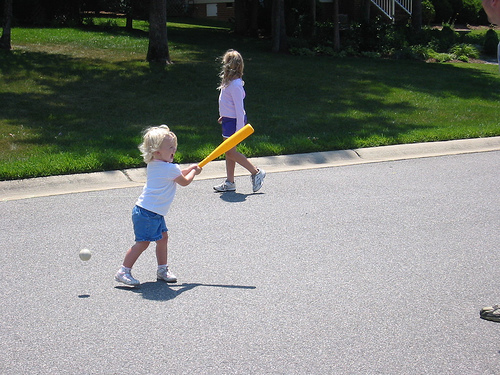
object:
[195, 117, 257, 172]
bat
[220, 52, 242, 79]
hair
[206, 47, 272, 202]
girl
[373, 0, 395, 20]
rail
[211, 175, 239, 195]
shoe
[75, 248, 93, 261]
baseball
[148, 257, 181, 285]
foot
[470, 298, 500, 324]
person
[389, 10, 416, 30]
steps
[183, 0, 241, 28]
home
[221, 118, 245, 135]
shorts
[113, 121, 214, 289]
kids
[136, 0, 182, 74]
tree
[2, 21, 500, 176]
grass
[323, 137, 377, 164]
curb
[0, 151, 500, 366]
ground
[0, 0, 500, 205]
yard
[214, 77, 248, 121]
shirt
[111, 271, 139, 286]
sneakers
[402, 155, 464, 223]
right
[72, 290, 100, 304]
shadow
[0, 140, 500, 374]
pavement